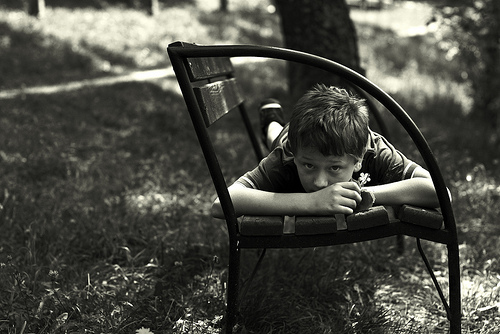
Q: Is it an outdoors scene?
A: Yes, it is outdoors.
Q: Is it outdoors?
A: Yes, it is outdoors.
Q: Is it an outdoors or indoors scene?
A: It is outdoors.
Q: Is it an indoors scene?
A: No, it is outdoors.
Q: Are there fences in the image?
A: No, there are no fences.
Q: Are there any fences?
A: No, there are no fences.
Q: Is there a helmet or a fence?
A: No, there are no fences or helmets.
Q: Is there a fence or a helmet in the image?
A: No, there are no fences or helmets.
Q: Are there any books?
A: No, there are no books.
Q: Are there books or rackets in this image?
A: No, there are no books or rackets.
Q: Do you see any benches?
A: Yes, there is a bench.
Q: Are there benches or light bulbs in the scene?
A: Yes, there is a bench.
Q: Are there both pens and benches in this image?
A: No, there is a bench but no pens.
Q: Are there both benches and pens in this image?
A: No, there is a bench but no pens.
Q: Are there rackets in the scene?
A: No, there are no rackets.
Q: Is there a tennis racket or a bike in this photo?
A: No, there are no rackets or bikes.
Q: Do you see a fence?
A: No, there are no fences.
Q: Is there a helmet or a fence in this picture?
A: No, there are no fences or helmets.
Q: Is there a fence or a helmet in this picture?
A: No, there are no fences or helmets.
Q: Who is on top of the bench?
A: The boy is on top of the bench.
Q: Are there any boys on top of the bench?
A: Yes, there is a boy on top of the bench.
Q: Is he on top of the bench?
A: Yes, the boy is on top of the bench.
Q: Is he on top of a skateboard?
A: No, the boy is on top of the bench.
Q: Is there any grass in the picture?
A: Yes, there is grass.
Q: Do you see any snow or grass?
A: Yes, there is grass.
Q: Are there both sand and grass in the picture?
A: No, there is grass but no sand.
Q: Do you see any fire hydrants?
A: No, there are no fire hydrants.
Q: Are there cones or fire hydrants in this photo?
A: No, there are no fire hydrants or cones.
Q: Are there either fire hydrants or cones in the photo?
A: No, there are no fire hydrants or cones.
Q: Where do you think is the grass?
A: The grass is on the hill.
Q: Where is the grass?
A: The grass is on the hill.